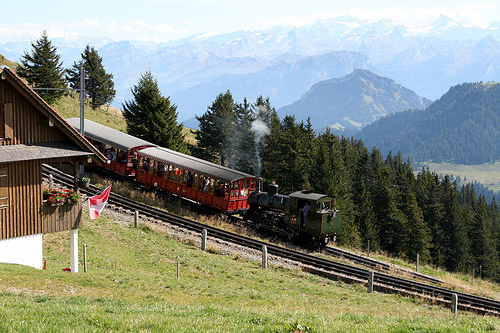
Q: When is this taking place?
A: Daytime.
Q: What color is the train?
A: Red and green.